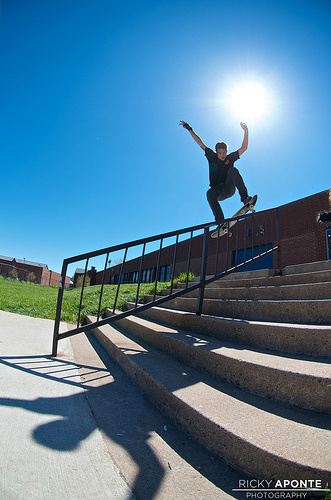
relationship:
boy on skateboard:
[173, 113, 253, 223] [207, 191, 258, 241]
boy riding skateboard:
[173, 113, 253, 223] [207, 191, 258, 241]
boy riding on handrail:
[173, 113, 253, 223] [52, 206, 286, 349]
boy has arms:
[173, 113, 253, 223] [173, 113, 249, 158]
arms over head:
[173, 113, 249, 158] [215, 141, 231, 164]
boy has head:
[173, 113, 253, 223] [215, 141, 231, 164]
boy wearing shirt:
[173, 113, 253, 223] [202, 147, 240, 185]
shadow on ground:
[1, 286, 253, 500] [4, 271, 327, 498]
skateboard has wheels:
[207, 191, 258, 241] [245, 202, 257, 219]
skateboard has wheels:
[207, 191, 258, 241] [223, 223, 233, 239]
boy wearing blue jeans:
[173, 113, 253, 223] [208, 165, 250, 221]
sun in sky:
[219, 71, 281, 129] [2, 0, 330, 199]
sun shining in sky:
[219, 71, 281, 129] [2, 0, 330, 199]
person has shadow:
[175, 108, 257, 221] [1, 286, 253, 500]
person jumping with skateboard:
[178, 118, 252, 226] [207, 191, 258, 241]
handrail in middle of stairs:
[52, 206, 286, 358] [80, 260, 327, 499]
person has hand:
[178, 118, 252, 226] [178, 117, 189, 131]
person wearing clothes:
[178, 118, 252, 226] [201, 149, 258, 217]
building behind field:
[96, 186, 328, 285] [1, 270, 200, 326]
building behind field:
[0, 253, 76, 288] [1, 270, 200, 326]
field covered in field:
[1, 270, 200, 326] [0, 270, 200, 326]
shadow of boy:
[1, 286, 253, 500] [173, 113, 253, 223]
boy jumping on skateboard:
[173, 113, 253, 223] [207, 191, 258, 241]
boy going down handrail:
[173, 113, 253, 223] [52, 206, 286, 358]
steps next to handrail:
[84, 253, 328, 498] [52, 206, 286, 358]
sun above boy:
[219, 71, 281, 129] [173, 113, 253, 223]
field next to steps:
[0, 270, 200, 326] [84, 253, 328, 498]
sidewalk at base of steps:
[0, 306, 258, 499] [84, 253, 328, 498]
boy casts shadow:
[173, 113, 253, 223] [1, 286, 253, 500]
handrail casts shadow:
[52, 206, 286, 358] [1, 286, 253, 500]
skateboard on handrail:
[207, 191, 258, 241] [52, 206, 286, 358]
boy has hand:
[173, 113, 253, 223] [178, 117, 194, 135]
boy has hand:
[173, 113, 253, 223] [236, 117, 252, 133]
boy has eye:
[173, 113, 253, 223] [217, 148, 224, 156]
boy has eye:
[173, 113, 253, 223] [222, 147, 227, 155]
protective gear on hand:
[183, 120, 194, 133] [178, 117, 194, 135]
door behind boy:
[232, 240, 273, 270] [173, 113, 253, 223]